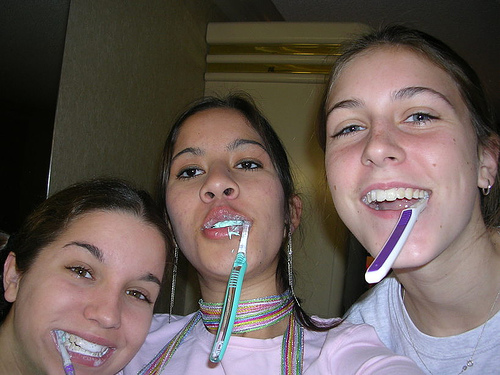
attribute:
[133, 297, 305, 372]
scarf — thin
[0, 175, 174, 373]
teeth — white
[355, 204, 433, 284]
toothbrush handle — blue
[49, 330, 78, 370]
toothbrush — purple, white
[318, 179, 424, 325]
handle — toothbrush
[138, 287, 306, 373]
scarf — colorful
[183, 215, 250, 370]
toothbrush — teal and white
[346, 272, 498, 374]
shirt — grey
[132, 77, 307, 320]
hair — dark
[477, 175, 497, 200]
black earrings — silver